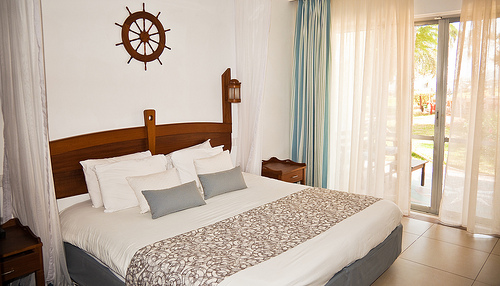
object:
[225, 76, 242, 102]
lantern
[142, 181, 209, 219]
cushion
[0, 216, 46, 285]
table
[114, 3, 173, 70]
wheel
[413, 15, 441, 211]
door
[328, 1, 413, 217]
curtains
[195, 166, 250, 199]
pillows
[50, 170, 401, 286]
cover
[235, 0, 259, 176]
net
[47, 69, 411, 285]
bed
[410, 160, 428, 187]
chair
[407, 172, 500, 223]
patio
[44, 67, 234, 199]
headboard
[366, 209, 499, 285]
floor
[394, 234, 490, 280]
tiles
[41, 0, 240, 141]
wall